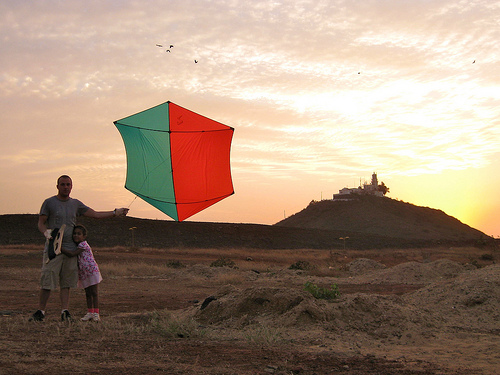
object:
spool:
[46, 221, 67, 261]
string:
[44, 222, 64, 263]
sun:
[462, 192, 500, 223]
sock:
[92, 307, 99, 314]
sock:
[86, 307, 94, 314]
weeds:
[182, 276, 463, 343]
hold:
[44, 222, 67, 262]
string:
[43, 196, 139, 268]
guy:
[27, 173, 129, 324]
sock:
[93, 308, 99, 313]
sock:
[87, 307, 93, 313]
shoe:
[89, 313, 103, 325]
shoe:
[78, 310, 94, 323]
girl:
[68, 220, 115, 310]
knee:
[89, 286, 98, 297]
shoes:
[57, 309, 78, 326]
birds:
[191, 56, 201, 66]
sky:
[0, 0, 500, 97]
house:
[331, 169, 393, 203]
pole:
[131, 230, 136, 249]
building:
[330, 170, 393, 200]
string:
[135, 126, 149, 180]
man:
[27, 170, 131, 321]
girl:
[58, 223, 107, 325]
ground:
[2, 241, 499, 373]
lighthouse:
[367, 171, 381, 186]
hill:
[271, 195, 500, 246]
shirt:
[36, 194, 88, 249]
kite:
[109, 95, 249, 232]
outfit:
[74, 240, 105, 292]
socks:
[60, 308, 70, 314]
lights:
[129, 227, 133, 230]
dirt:
[251, 281, 494, 375]